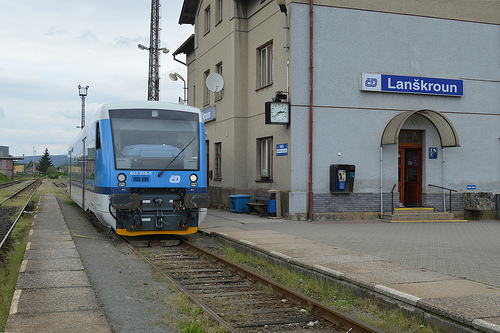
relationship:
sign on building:
[356, 72, 464, 97] [294, 2, 498, 220]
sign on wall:
[312, 59, 496, 101] [284, 0, 499, 220]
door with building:
[401, 149, 424, 207] [168, 2, 484, 215]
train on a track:
[67, 101, 213, 247] [119, 235, 374, 332]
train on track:
[58, 94, 215, 244] [138, 241, 375, 331]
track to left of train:
[0, 175, 41, 261] [9, 60, 221, 266]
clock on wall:
[257, 87, 297, 133] [243, 17, 313, 220]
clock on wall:
[264, 90, 290, 125] [171, 0, 289, 217]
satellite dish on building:
[204, 70, 223, 90] [168, 2, 484, 215]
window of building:
[209, 29, 331, 119] [172, 1, 291, 217]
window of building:
[252, 130, 289, 186] [172, 1, 291, 217]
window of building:
[253, 37, 273, 92] [194, 0, 470, 216]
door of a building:
[398, 129, 426, 207] [168, 2, 484, 215]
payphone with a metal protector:
[328, 153, 365, 210] [315, 148, 373, 204]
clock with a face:
[264, 90, 290, 125] [269, 103, 286, 123]